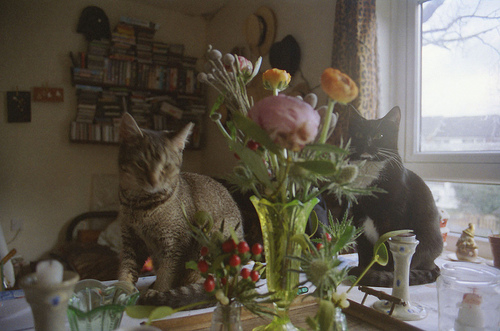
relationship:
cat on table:
[110, 114, 246, 307] [5, 245, 499, 330]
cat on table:
[326, 100, 440, 282] [5, 245, 499, 330]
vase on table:
[245, 196, 314, 330] [5, 245, 499, 330]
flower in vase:
[254, 96, 305, 203] [245, 196, 314, 330]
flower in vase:
[304, 66, 354, 206] [245, 196, 314, 330]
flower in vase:
[259, 65, 295, 226] [245, 196, 314, 330]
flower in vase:
[196, 46, 275, 222] [245, 196, 314, 330]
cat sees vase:
[110, 114, 246, 307] [245, 196, 314, 330]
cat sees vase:
[326, 100, 440, 282] [245, 196, 314, 330]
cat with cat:
[110, 114, 246, 307] [326, 100, 440, 282]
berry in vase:
[202, 279, 220, 295] [202, 287, 253, 331]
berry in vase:
[248, 267, 261, 283] [202, 287, 253, 331]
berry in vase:
[251, 239, 262, 256] [202, 287, 253, 331]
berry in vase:
[229, 255, 239, 271] [202, 287, 253, 331]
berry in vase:
[222, 238, 237, 255] [202, 287, 253, 331]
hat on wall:
[268, 36, 300, 81] [205, 11, 352, 230]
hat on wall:
[246, 2, 276, 55] [205, 11, 352, 230]